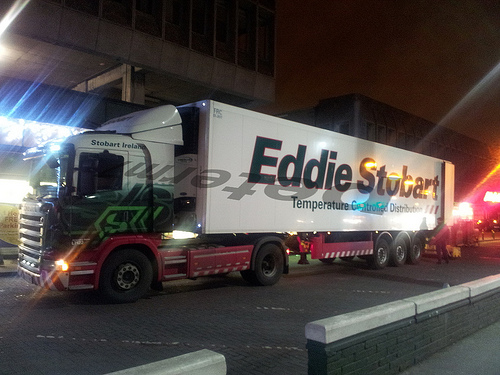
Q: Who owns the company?
A: Eddie Stobart.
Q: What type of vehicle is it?
A: Tractor trailer.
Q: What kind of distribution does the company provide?
A: Temperature controlled.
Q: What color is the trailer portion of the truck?
A: White.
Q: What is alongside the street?
A: Brick wall.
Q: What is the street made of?
A: Stones and bricks.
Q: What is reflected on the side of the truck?
A: Words.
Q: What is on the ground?
A: Wall.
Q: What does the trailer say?
A: Eddie Stobart.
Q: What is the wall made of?
A: Bricks and stone.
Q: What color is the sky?
A: Dark.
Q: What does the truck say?
A: Eddie Stobart.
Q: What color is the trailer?
A: White.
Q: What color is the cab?
A: White, green and red.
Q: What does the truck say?
A: Eddie Stobart.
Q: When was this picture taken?
A: Evening.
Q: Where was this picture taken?
A: A truck stop.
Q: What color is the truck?
A: White.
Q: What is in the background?
A: Lights.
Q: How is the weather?
A: Clear.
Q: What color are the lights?
A: Red.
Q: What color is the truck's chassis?
A: Red.